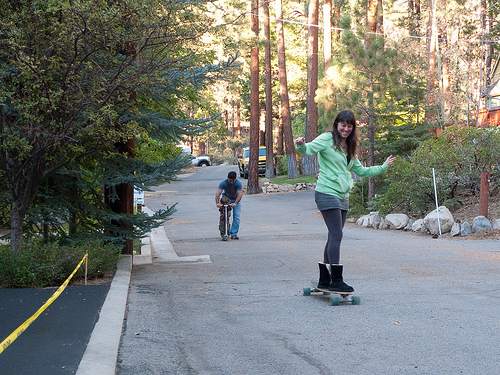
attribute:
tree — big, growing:
[13, 11, 188, 262]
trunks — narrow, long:
[241, 7, 307, 195]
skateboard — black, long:
[311, 279, 360, 308]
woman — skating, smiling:
[303, 113, 377, 286]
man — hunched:
[218, 170, 252, 205]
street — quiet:
[172, 146, 285, 374]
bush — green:
[19, 237, 121, 266]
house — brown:
[437, 87, 500, 167]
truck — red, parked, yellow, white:
[240, 139, 282, 172]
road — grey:
[236, 149, 292, 296]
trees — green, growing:
[37, 36, 241, 167]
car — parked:
[235, 132, 277, 180]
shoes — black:
[318, 262, 354, 293]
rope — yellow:
[9, 255, 89, 327]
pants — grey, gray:
[317, 215, 348, 261]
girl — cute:
[309, 113, 373, 206]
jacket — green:
[315, 143, 366, 195]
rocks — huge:
[370, 207, 482, 231]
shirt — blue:
[221, 210, 235, 220]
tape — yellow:
[17, 256, 85, 343]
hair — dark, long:
[343, 109, 360, 136]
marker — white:
[158, 221, 205, 272]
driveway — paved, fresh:
[4, 288, 67, 371]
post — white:
[427, 170, 446, 244]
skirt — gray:
[309, 189, 354, 211]